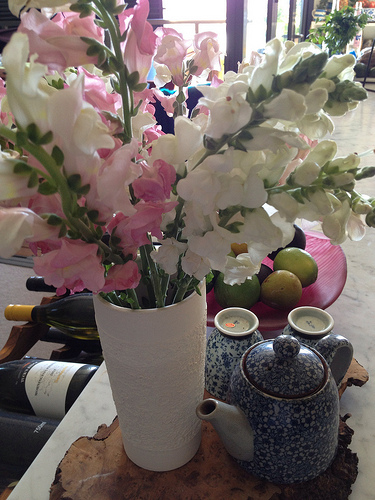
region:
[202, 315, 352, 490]
blue floral kettle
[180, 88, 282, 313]
white flowers in a vase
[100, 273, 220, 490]
white vase with flowers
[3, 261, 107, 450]
three bottles of wine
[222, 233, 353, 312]
fruit on a pink plate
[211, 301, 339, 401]
two upside down tea cups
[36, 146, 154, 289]
flowers with pink petals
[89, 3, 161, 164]
green stem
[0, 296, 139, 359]
wine bottle with yellow cap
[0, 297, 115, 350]
wine bottle with no label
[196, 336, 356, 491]
A blue and white teapot.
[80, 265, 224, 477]
A white vase.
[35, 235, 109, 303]
A pink flower.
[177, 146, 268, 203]
A white flower.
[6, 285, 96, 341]
A wine bottle on its side.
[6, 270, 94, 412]
Several wine bottles next to each other.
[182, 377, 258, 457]
The spout of the tea pot.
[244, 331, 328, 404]
The top of the tea pot.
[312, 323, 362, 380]
The handle of the teapot.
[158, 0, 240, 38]
A window in the background.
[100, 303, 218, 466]
the vase is white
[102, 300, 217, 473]
the vase is plaster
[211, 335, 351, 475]
the teapot is speckled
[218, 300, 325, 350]
two teacups beside teapot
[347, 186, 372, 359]
the counter is marble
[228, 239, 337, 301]
the fruit is in dish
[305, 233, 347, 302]
the dish is pink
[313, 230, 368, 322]
the dish is on counter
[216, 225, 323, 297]
the fruit is green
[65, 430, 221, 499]
the mat is brown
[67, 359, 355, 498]
Brown wood on a table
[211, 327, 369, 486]
Blue and white tea pot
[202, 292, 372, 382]
Blue and white cups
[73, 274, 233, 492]
White vase on a wood slab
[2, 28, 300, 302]
Pink and white flowers in a vase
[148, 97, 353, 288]
White flowers in a vase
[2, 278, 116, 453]
Bottles of wine by a table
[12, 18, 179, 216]
Pink flowers in a vase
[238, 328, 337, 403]
Blue and white lid on a teapot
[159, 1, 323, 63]
Glass windows in a room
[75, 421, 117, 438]
brown edge of wood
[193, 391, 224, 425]
lid of blue and white pot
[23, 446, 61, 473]
white edge of marble table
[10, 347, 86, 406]
white label on black wine bottle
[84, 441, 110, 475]
small line in brown wood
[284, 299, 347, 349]
candle wick in blue candle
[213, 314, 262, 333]
orange paper in pot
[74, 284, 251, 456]
large white vase on table top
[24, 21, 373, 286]
large white and pink flowers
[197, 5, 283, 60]
purple column in the back ground